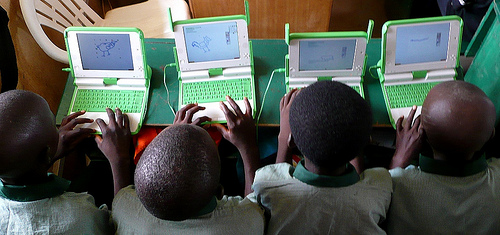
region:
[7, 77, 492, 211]
A row of kids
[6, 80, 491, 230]
A row of four kids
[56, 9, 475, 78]
A row of computers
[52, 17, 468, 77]
A row of four computers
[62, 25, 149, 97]
The computer is on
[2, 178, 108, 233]
Green and grey shirt of a kid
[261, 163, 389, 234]
Grey and green shirt of a kid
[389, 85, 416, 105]
Keyboard of the laptop is green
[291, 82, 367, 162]
The kid has short hair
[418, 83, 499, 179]
The kid has no hair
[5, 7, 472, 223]
a bunch of kids on laptops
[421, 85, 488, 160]
the head of a black child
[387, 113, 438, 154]
the hand of a black child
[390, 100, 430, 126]
the fingers of a black child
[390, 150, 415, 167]
the wrist of a black child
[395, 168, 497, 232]
the shirt of a black child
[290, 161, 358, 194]
the collar of a black child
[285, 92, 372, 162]
the hair of a black child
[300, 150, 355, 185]
the neck of a black child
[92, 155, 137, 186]
the arm of a black child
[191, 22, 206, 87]
There is a laptop here that is green and white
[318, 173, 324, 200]
This boy is wearing a green shirt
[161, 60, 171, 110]
There is a hookup here for electricity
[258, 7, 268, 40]
There is a cabinet that is visible here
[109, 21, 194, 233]
This photo was taken in Africa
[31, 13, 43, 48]
There is a white chair here that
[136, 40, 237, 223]
This photo has a great deal of detail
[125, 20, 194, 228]
This photo was taken last week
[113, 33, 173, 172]
This photo really looks great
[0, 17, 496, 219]
four black children using green and white laptops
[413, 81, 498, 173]
bald head of one of the students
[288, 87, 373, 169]
black hair of one of the students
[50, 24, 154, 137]
small open green and white laptop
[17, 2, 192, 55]
white plastic chair next to the small green table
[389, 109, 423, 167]
the left hand of one of the students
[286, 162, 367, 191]
green collar on the shirt of one of the students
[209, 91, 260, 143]
right hand and fingers of one of the students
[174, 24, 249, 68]
small white screen on one of the laptops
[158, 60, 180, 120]
white power cord coming from one of the laptops